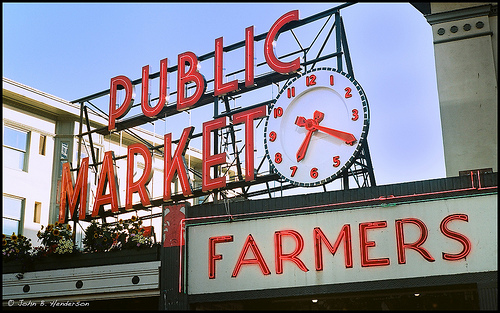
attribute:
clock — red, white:
[265, 70, 368, 187]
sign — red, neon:
[180, 190, 499, 295]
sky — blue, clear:
[3, 5, 447, 200]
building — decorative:
[4, 77, 248, 253]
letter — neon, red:
[275, 229, 308, 274]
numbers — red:
[307, 73, 316, 85]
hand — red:
[295, 114, 357, 144]